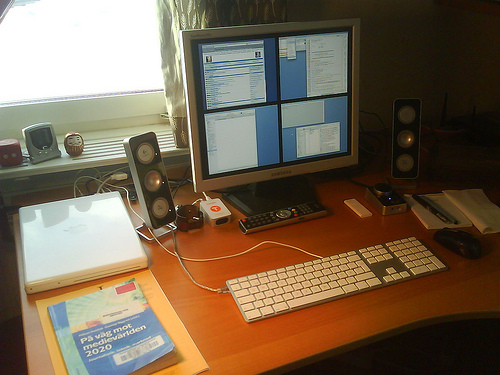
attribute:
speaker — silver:
[119, 127, 181, 253]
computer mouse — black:
[432, 223, 489, 266]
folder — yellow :
[15, 250, 208, 371]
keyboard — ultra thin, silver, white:
[225, 233, 452, 325]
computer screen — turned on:
[180, 27, 359, 177]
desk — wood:
[401, 280, 465, 315]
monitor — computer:
[178, 16, 362, 216]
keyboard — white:
[208, 232, 459, 320]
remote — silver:
[230, 200, 342, 235]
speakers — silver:
[96, 126, 173, 256]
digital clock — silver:
[21, 118, 63, 164]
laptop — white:
[10, 186, 148, 297]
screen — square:
[181, 15, 363, 192]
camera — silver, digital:
[361, 182, 410, 222]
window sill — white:
[3, 67, 172, 150]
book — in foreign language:
[40, 272, 184, 374]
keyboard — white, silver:
[177, 209, 454, 347]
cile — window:
[1, 97, 198, 189]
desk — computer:
[0, 153, 467, 373]